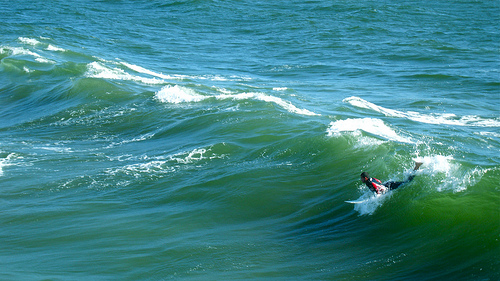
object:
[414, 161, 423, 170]
foot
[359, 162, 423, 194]
surfer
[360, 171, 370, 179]
hair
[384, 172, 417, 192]
pants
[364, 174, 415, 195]
wet suit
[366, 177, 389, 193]
shirt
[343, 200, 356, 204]
tip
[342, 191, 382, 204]
surfboard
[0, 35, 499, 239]
wave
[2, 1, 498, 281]
water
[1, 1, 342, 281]
ocean water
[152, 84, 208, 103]
foam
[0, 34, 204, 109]
white caps